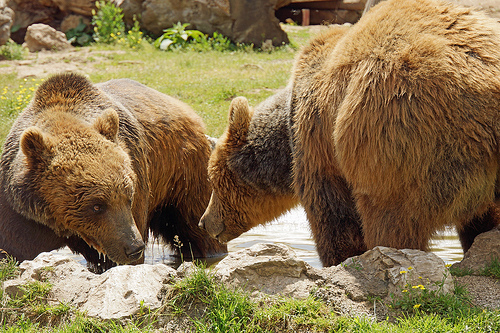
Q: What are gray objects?
A: Rocks.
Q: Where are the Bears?
A: Together.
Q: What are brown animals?
A: Bears.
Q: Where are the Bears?
A: In water.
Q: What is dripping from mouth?
A: Water.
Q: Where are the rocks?
A: Next to bear.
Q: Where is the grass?
A: Next to rocks.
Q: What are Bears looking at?
A: Each other.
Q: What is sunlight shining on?
A: Grass.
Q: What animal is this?
A: Bear.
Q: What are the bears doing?
A: Looking at each other.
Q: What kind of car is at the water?
A: No car.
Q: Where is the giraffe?
A: No giraffe.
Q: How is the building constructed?
A: No building.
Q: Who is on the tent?
A: No tent.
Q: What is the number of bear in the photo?
A: Two.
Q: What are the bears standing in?
A: Water.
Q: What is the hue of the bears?
A: Brown.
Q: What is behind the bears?
A: Grass.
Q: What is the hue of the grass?
A: Green.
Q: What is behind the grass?
A: Rocks.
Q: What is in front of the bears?
A: Rocks.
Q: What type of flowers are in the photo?
A: Dandelions.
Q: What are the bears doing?
A: Looking at each other.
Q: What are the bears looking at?
A: Each other.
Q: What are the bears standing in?
A: Water.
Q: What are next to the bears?
A: Rocks.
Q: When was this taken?
A: Daytime.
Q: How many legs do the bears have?
A: 4.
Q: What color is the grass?
A: Green.